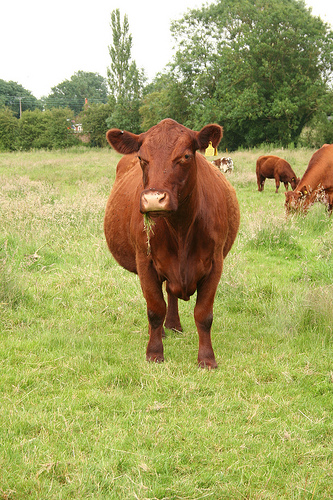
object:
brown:
[267, 158, 279, 170]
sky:
[2, 0, 331, 85]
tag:
[205, 141, 214, 157]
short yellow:
[22, 410, 56, 427]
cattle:
[103, 118, 240, 370]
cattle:
[256, 155, 301, 194]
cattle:
[284, 142, 333, 220]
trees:
[0, 1, 332, 151]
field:
[0, 147, 333, 499]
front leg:
[193, 253, 223, 353]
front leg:
[135, 249, 167, 357]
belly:
[103, 180, 241, 275]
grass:
[142, 213, 157, 258]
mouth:
[139, 206, 169, 216]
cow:
[211, 157, 233, 174]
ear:
[191, 123, 223, 153]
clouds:
[0, 0, 184, 60]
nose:
[141, 189, 170, 212]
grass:
[0, 148, 333, 497]